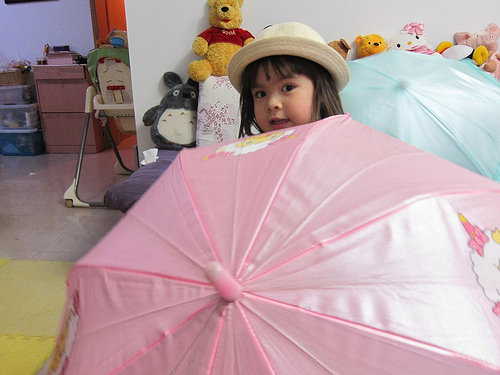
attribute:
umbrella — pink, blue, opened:
[37, 108, 500, 374]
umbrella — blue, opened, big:
[326, 47, 499, 182]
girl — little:
[223, 16, 353, 138]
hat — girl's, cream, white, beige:
[227, 22, 351, 93]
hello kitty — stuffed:
[387, 20, 440, 64]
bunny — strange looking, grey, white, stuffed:
[142, 67, 205, 154]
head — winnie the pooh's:
[203, 1, 247, 29]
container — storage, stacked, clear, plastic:
[1, 129, 43, 155]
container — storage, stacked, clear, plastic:
[1, 106, 41, 131]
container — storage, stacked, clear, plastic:
[2, 84, 35, 104]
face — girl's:
[250, 60, 319, 135]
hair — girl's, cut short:
[233, 56, 345, 140]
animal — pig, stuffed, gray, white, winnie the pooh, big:
[453, 18, 500, 88]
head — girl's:
[238, 53, 346, 137]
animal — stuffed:
[140, 68, 206, 152]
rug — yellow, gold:
[4, 254, 88, 367]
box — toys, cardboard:
[3, 54, 31, 85]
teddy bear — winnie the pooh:
[184, 1, 268, 82]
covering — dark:
[104, 145, 184, 212]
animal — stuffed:
[189, 0, 263, 81]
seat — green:
[84, 46, 135, 108]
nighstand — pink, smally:
[32, 71, 95, 148]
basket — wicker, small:
[1, 65, 32, 87]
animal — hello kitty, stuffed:
[381, 26, 436, 68]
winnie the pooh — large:
[186, 0, 266, 85]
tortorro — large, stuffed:
[132, 68, 203, 152]